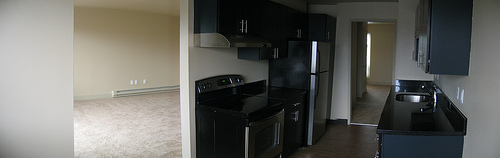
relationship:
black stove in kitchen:
[193, 75, 279, 154] [195, 0, 494, 155]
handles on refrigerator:
[308, 37, 316, 140] [267, 10, 341, 155]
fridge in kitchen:
[267, 37, 333, 147] [195, 0, 494, 155]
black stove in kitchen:
[193, 75, 314, 157] [191, 6, 496, 147]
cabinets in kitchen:
[218, 12, 318, 54] [199, 12, 481, 144]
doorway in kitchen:
[350, 18, 386, 82] [195, 0, 494, 155]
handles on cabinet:
[240, 17, 250, 38] [220, 5, 277, 42]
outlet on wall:
[453, 83, 474, 111] [89, 13, 193, 97]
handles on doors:
[240, 19, 248, 33] [198, 7, 291, 42]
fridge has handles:
[267, 37, 333, 147] [264, 20, 343, 150]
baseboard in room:
[108, 75, 185, 102] [2, 2, 492, 151]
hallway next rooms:
[353, 31, 387, 111] [333, 14, 403, 156]